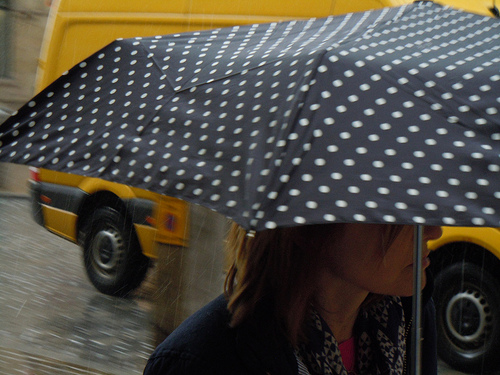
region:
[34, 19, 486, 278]
black fabric umbrella with white spots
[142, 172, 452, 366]
woman in scarf uner umbrella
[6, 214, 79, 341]
rain falling from the sky on the ground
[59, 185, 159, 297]
black rubber tire on silver wheel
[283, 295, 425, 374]
black and white patterned scarf on neck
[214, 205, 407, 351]
medium length brown straight hair on woman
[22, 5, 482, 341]
large yellow van behind the woman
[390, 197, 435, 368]
chrome post for the handle on umbrella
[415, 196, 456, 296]
woman's nose and lips under umbrella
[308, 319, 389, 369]
pink shirt sticking out of coat and scarf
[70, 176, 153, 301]
Tire of a van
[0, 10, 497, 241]
Black and white polka dots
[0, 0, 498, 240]
Unfurled umbrella in the street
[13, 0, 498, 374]
Yellow colored van on the street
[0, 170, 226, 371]
Rain drops on the street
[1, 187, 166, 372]
Black color of tarmac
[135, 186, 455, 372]
Woman under the umbrella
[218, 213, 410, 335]
Brown hair of a woman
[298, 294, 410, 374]
Scarf on the neck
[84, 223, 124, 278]
Rim of a van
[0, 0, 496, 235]
a black umbrella with white dots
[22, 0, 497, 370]
a yellow van with gray trim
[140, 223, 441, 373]
a woman with red colored hair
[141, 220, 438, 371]
a woman wearing a scarf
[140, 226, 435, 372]
a woman with dark hair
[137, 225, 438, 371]
a woman wearing a pink shirt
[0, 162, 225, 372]
rain falling from the sky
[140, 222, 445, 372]
woman facing the right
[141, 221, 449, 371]
woman with a dark jacket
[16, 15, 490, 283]
yellow van on the street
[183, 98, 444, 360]
person holding a umbrella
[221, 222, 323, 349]
person with brown hair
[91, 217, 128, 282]
gray rims on a van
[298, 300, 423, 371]
woman wearing a scarf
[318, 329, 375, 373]
woman wearing a pink shirt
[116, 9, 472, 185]
black and white umbrella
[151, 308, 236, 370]
woman wearing a blue jacket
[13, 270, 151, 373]
water on the asphalt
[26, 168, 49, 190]
reflector on a van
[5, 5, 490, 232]
black umbrella with white polka dots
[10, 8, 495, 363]
yellow car on the street behind the woman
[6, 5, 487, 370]
woman is holding an umbrella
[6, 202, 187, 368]
heavy rain hitting the streets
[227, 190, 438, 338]
woman has dark hair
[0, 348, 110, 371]
a corner of the sidewalk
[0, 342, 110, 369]
a bricked sidewalk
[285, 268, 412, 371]
woman wearing scarf around her neck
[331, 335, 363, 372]
woman is wearing pink shirt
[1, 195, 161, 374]
an asphalt street